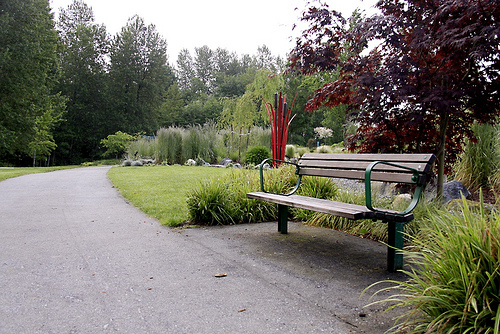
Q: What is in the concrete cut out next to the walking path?
A: Bench.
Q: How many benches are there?
A: One.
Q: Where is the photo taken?
A: Park.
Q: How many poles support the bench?
A: Two.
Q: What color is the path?
A: Grey.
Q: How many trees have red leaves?
A: One.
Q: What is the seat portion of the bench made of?
A: Wood.